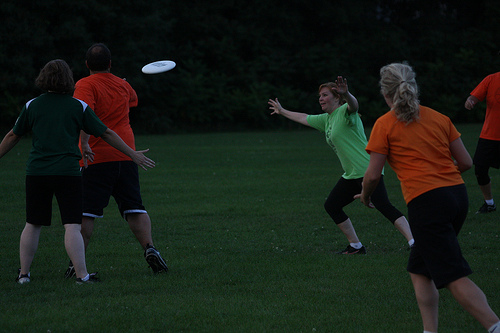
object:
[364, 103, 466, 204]
shirt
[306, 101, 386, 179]
shirt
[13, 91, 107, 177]
shirt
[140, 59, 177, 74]
frisbee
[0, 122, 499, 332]
grass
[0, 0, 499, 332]
park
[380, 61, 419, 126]
hair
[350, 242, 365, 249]
socks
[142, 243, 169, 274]
shoes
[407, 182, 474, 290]
shorts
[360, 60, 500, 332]
lady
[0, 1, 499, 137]
trees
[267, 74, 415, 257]
woman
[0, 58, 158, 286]
people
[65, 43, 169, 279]
man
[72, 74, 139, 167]
shirt